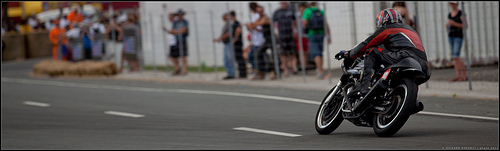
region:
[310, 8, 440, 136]
motorcycle and rider with red and black jacket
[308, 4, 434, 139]
person riding motorcycle leaning right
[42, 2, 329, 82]
people standing on a sidewalk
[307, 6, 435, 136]
racing style motorcycle with rider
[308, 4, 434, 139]
person wearing black and red jacket and helmet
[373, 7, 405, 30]
black and red patterned motorcycle helmet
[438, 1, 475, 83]
woman in black tank top and capri jeans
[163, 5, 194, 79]
two people standing on sidewalk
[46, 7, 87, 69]
two men in orange jumpsuits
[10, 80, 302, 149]
asphalt road with white dotted line strip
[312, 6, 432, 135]
Person riding a motorcycle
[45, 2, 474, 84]
People watching from a sidewalk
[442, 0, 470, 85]
Woman wearing a black shirt and blue jeans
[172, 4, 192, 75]
Man wearing a cowboy hat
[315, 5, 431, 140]
Person riding a black motorcycle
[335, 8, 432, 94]
Person wearing red and black clothing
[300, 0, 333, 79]
Man wearing a green shirt and backpack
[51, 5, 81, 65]
Two people in orange clothing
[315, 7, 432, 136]
Person steering their motorcycle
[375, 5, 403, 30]
Black and red helmet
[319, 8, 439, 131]
person riding a motorcycle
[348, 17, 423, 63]
person with red and black jacket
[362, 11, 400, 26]
helmet on the rider's head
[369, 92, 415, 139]
big tires on the rear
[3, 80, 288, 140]
white lines in the road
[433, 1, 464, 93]
girl standing on the street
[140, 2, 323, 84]
people waiting along side the road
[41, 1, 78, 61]
two men in orange suits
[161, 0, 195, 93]
two people standing together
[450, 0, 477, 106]
pole in the ground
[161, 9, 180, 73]
person is standing next to person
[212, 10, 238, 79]
person is standing next to person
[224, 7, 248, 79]
person is standing next to person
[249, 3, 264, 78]
person is standing next to person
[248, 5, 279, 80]
person is standing next to person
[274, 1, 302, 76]
person is standing next to person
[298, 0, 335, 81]
person is standing next to person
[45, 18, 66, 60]
person is standing next to person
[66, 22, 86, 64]
person is standing next to person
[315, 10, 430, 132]
biker in the middle of an empty street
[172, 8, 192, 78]
person is standing by on the sidewalk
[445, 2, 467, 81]
person is standing by on the sidewalk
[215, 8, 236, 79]
person is standing by on the sidewalk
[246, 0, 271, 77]
persons are standing by on the sidewalk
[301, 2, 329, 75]
man walking on sidewalk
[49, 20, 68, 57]
person wearing bright orange suit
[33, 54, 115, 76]
bales of straw lined up in the street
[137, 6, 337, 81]
a fence separates the sidewalk from the street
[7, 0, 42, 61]
yellow large signs sitting on pole